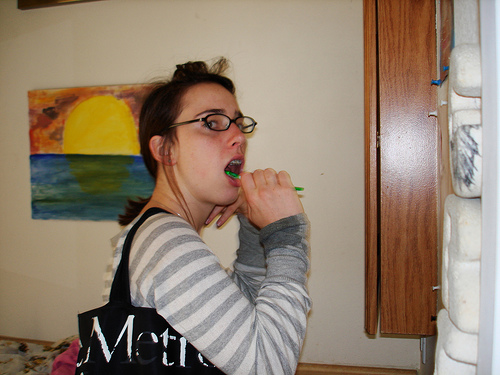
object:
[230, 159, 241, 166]
teeth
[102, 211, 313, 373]
gray/whiteshirt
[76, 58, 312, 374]
girl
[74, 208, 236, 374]
tote bag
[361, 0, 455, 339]
cabinet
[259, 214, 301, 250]
wet sleeve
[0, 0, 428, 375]
wall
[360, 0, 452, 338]
oak cabinet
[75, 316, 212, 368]
letters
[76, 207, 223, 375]
bag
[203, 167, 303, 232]
hand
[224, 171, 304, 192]
toothbrush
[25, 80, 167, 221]
painting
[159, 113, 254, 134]
glasses